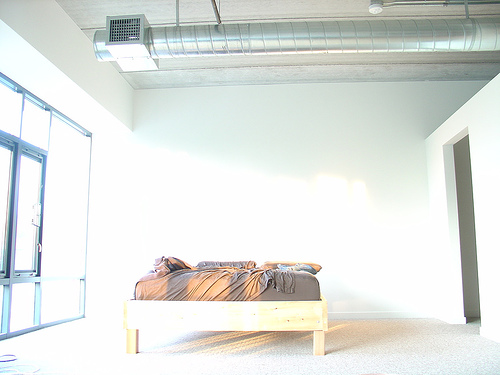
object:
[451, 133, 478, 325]
door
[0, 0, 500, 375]
room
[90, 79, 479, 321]
wall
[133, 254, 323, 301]
blanket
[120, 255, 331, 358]
bed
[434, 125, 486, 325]
doorway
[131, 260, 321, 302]
sheets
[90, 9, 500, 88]
vent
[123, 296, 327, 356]
bedframe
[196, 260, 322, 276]
pillows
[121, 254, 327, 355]
frame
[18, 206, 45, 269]
latch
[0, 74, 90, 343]
window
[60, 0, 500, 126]
ceiling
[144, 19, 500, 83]
ducting